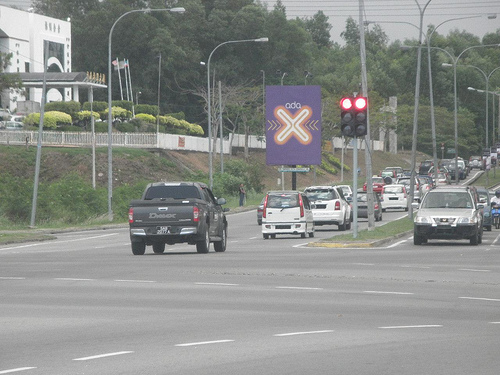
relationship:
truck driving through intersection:
[125, 178, 230, 256] [6, 95, 499, 370]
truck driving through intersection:
[125, 178, 230, 256] [3, 209, 498, 374]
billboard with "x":
[263, 85, 320, 168] [272, 104, 312, 143]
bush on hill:
[37, 108, 78, 128] [24, 101, 109, 170]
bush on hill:
[33, 111, 75, 128] [41, 104, 116, 154]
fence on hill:
[0, 128, 384, 156] [2, 143, 434, 224]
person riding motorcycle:
[474, 176, 482, 191] [471, 171, 499, 238]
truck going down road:
[125, 178, 230, 256] [1, 154, 498, 374]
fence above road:
[1, 127, 386, 157] [1, 154, 498, 374]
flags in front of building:
[116, 50, 146, 115] [4, 9, 77, 121]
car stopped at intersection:
[412, 188, 482, 243] [2, 231, 499, 373]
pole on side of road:
[106, 8, 172, 223] [27, 155, 482, 255]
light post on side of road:
[362, 15, 497, 183] [27, 155, 482, 255]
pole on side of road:
[205, 38, 256, 194] [27, 155, 482, 255]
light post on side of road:
[438, 59, 499, 172] [27, 155, 482, 255]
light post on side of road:
[404, 0, 439, 217] [27, 155, 482, 255]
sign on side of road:
[265, 84, 322, 167] [1, 154, 498, 374]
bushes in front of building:
[83, 98, 219, 128] [6, 18, 86, 131]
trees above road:
[238, 17, 433, 125] [28, 156, 458, 373]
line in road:
[0, 271, 500, 303] [0, 154, 499, 375]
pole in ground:
[20, 36, 48, 239] [1, 133, 498, 370]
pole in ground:
[96, 1, 189, 226] [1, 133, 498, 370]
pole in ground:
[190, 29, 273, 207] [1, 133, 498, 370]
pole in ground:
[351, 1, 392, 234] [1, 133, 498, 370]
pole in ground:
[346, 136, 366, 240] [1, 133, 498, 370]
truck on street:
[125, 178, 230, 256] [5, 247, 484, 368]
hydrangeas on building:
[29, 100, 206, 136] [19, 7, 171, 183]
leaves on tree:
[277, 35, 329, 74] [143, 13, 408, 108]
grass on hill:
[64, 194, 84, 214] [2, 143, 434, 224]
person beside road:
[234, 178, 249, 209] [1, 154, 498, 374]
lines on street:
[0, 275, 498, 303] [0, 231, 498, 373]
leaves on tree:
[130, 22, 195, 64] [132, 3, 216, 126]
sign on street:
[260, 83, 320, 167] [5, 247, 484, 368]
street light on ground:
[92, 4, 203, 181] [5, 245, 484, 373]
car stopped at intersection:
[412, 188, 482, 243] [280, 212, 476, 372]